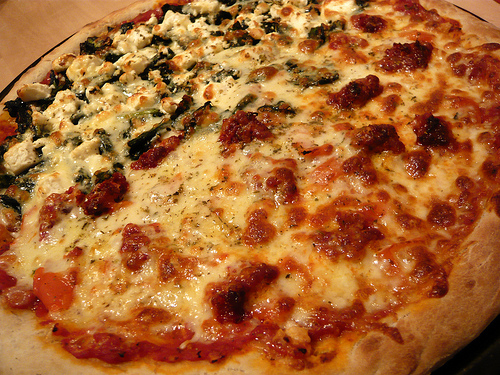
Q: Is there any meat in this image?
A: Yes, there is meat.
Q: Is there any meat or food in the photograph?
A: Yes, there is meat.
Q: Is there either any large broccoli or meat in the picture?
A: Yes, there is large meat.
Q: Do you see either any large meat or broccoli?
A: Yes, there is large meat.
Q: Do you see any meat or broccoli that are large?
A: Yes, the meat is large.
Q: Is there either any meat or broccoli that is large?
A: Yes, the meat is large.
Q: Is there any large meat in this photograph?
A: Yes, there is large meat.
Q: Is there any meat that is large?
A: Yes, there is meat that is large.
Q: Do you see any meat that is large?
A: Yes, there is meat that is large.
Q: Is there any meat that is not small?
A: Yes, there is large meat.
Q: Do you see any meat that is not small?
A: Yes, there is large meat.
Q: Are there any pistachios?
A: No, there are no pistachios.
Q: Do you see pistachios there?
A: No, there are no pistachios.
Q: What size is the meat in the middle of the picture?
A: The meat is large.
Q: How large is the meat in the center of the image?
A: The meat is large.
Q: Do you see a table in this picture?
A: Yes, there is a table.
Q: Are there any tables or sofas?
A: Yes, there is a table.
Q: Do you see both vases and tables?
A: No, there is a table but no vases.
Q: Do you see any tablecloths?
A: No, there are no tablecloths.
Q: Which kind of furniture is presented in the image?
A: The furniture is a table.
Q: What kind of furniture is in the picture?
A: The furniture is a table.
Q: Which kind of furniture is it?
A: The piece of furniture is a table.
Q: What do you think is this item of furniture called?
A: This is a table.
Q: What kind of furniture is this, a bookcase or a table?
A: This is a table.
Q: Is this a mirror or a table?
A: This is a table.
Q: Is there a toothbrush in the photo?
A: No, there are no toothbrushes.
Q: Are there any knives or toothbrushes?
A: No, there are no toothbrushes or knives.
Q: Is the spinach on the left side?
A: Yes, the spinach is on the left of the image.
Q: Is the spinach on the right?
A: No, the spinach is on the left of the image.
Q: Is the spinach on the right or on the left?
A: The spinach is on the left of the image.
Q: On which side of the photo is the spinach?
A: The spinach is on the left of the image.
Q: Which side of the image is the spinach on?
A: The spinach is on the left of the image.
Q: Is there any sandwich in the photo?
A: No, there are no sandwiches.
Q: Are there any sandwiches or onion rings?
A: No, there are no sandwiches or onion rings.